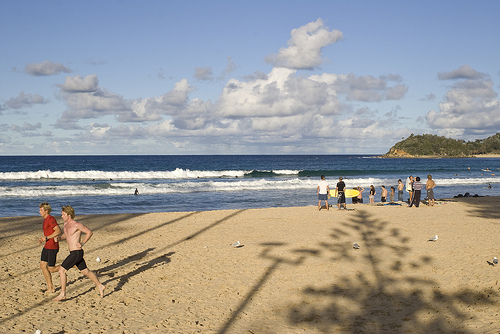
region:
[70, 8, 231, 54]
this is the sky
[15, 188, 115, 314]
these are men running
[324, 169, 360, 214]
the man is holding a surfing board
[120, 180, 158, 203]
the man is swimming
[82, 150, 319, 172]
this is an ocean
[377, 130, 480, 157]
this is a mountain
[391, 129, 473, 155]
the mountain has trees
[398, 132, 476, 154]
the trees are green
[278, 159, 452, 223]
these are people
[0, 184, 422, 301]
this is a beach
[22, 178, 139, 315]
Two guys are running.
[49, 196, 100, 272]
The guy isn't wearing a shirt.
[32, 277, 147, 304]
The guys aren't wearing shoes.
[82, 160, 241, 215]
People in the water.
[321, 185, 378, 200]
A guy holding a surfboard.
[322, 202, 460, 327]
A tree is casting a shadow.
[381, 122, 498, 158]
Island in the distance.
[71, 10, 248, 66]
The sky is blue.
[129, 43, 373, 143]
Clouds in the sky.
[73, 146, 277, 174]
The water is blue.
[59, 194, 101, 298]
this is a man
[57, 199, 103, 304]
the man is running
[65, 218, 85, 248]
the man is bare chested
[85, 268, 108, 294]
the right foot is behind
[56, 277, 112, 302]
the man is bare footed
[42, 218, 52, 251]
the t shirt is red in color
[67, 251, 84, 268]
the shorts are black in color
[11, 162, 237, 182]
waves are on the sea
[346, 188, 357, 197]
this is a surf board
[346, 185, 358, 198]
the surf board is yellow in color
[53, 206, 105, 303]
shirtless man is running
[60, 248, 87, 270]
man wearing black shorts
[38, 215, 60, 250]
man wearing red t-shirt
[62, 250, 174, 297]
shirtless man casts a shadow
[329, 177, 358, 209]
person carrying yellow surfboard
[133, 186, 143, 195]
person in the water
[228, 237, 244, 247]
seagull on the sand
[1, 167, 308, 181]
wave in the water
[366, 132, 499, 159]
hill visible beyond water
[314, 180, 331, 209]
person wearing white shirt standing near water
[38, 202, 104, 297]
two men running on the beach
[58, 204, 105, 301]
man without a shirt running on the beach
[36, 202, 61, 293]
man in red shirt running on the beach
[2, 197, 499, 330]
sand on the beach is tan in color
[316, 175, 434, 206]
group of people facing the water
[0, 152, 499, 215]
water is blue with white waves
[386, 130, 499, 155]
A mountain to the right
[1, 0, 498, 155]
Sky is blue with white clouds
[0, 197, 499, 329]
dark shadows in sand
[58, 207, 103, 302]
man running in only shorts